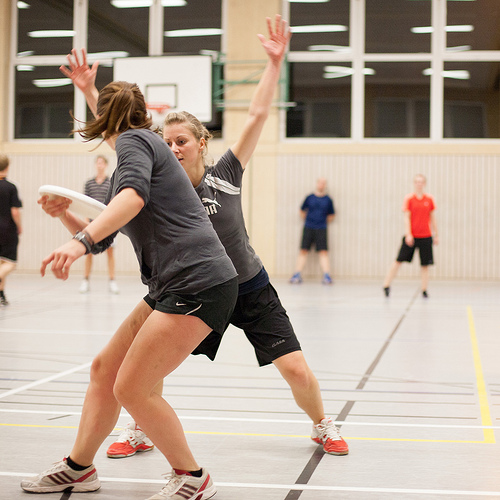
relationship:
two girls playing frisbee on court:
[16, 10, 350, 499] [2, 268, 497, 498]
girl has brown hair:
[18, 80, 240, 499] [69, 79, 156, 158]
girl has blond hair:
[57, 13, 352, 460] [151, 111, 218, 173]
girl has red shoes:
[57, 13, 352, 460] [107, 417, 352, 465]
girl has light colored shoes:
[18, 80, 240, 499] [21, 457, 217, 499]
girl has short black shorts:
[18, 80, 240, 499] [141, 268, 239, 333]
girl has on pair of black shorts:
[18, 80, 240, 499] [141, 268, 239, 333]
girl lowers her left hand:
[18, 80, 240, 499] [40, 240, 88, 279]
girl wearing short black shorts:
[18, 80, 240, 499] [141, 268, 239, 333]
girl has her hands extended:
[57, 13, 352, 460] [61, 12, 292, 175]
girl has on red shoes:
[57, 13, 352, 460] [107, 417, 352, 465]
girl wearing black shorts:
[57, 13, 352, 460] [193, 267, 308, 370]